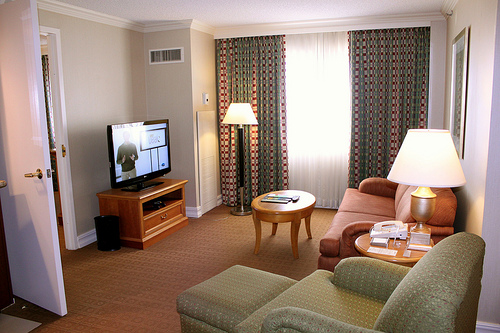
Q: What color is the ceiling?
A: White.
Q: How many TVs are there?
A: One.